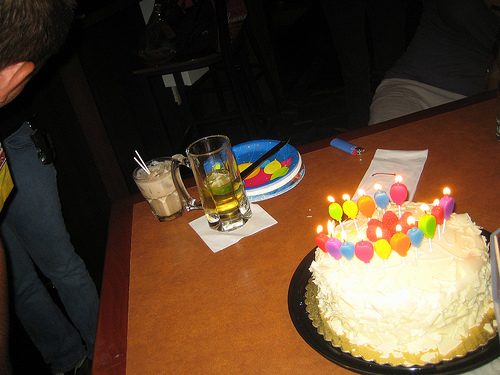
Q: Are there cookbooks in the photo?
A: No, there are no cookbooks.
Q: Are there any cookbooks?
A: No, there are no cookbooks.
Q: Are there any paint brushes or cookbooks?
A: No, there are no cookbooks or paint brushes.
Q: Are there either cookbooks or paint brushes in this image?
A: No, there are no cookbooks or paint brushes.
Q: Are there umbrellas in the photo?
A: No, there are no umbrellas.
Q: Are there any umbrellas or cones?
A: No, there are no umbrellas or cones.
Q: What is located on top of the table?
A: The paper is on top of the table.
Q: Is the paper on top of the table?
A: Yes, the paper is on top of the table.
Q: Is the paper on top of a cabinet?
A: No, the paper is on top of the table.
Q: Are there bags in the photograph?
A: No, there are no bags.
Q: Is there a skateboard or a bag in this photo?
A: No, there are no bags or skateboards.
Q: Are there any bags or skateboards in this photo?
A: No, there are no bags or skateboards.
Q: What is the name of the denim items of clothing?
A: The clothing items are jeans.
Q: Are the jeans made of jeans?
A: Yes, the jeans are made of jeans.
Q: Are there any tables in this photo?
A: Yes, there is a table.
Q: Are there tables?
A: Yes, there is a table.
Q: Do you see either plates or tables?
A: Yes, there is a table.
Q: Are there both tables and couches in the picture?
A: No, there is a table but no couches.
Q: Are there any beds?
A: No, there are no beds.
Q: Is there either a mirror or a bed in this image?
A: No, there are no beds or mirrors.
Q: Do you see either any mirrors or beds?
A: No, there are no beds or mirrors.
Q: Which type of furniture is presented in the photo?
A: The furniture is a table.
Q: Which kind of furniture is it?
A: The piece of furniture is a table.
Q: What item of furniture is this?
A: This is a table.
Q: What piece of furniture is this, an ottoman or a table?
A: This is a table.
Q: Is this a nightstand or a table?
A: This is a table.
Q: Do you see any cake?
A: Yes, there is a cake.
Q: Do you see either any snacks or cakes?
A: Yes, there is a cake.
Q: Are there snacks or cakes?
A: Yes, there is a cake.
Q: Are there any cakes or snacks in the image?
A: Yes, there is a cake.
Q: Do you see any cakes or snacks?
A: Yes, there is a cake.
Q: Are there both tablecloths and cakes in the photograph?
A: No, there is a cake but no tablecloths.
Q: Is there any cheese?
A: No, there is no cheese.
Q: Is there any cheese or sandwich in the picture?
A: No, there are no cheese or sandwiches.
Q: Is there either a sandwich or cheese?
A: No, there are no cheese or sandwiches.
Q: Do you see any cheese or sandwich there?
A: No, there are no cheese or sandwiches.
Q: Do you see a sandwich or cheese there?
A: No, there are no cheese or sandwiches.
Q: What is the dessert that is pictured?
A: The dessert is a cake.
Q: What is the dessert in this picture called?
A: The dessert is a cake.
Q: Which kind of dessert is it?
A: The dessert is a cake.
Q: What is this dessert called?
A: This is a cake.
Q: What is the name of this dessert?
A: This is a cake.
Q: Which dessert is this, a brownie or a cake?
A: This is a cake.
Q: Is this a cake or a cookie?
A: This is a cake.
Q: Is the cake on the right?
A: Yes, the cake is on the right of the image.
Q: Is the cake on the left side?
A: No, the cake is on the right of the image.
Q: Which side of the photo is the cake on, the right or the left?
A: The cake is on the right of the image.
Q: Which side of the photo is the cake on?
A: The cake is on the right of the image.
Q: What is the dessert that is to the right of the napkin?
A: The dessert is a cake.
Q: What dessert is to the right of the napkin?
A: The dessert is a cake.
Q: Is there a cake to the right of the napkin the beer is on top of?
A: Yes, there is a cake to the right of the napkin.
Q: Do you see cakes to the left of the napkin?
A: No, the cake is to the right of the napkin.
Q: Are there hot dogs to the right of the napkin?
A: No, there is a cake to the right of the napkin.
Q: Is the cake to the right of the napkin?
A: Yes, the cake is to the right of the napkin.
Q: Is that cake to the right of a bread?
A: No, the cake is to the right of the napkin.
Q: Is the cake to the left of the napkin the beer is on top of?
A: No, the cake is to the right of the napkin.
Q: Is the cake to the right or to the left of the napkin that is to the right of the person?
A: The cake is to the right of the napkin.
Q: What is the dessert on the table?
A: The dessert is a cake.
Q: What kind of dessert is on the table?
A: The dessert is a cake.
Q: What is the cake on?
A: The cake is on the table.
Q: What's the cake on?
A: The cake is on the table.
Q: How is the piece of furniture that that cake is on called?
A: The piece of furniture is a table.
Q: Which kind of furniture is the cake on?
A: The cake is on the table.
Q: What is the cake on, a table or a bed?
A: The cake is on a table.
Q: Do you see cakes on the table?
A: Yes, there is a cake on the table.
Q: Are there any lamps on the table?
A: No, there is a cake on the table.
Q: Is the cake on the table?
A: Yes, the cake is on the table.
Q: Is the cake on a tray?
A: No, the cake is on the table.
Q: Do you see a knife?
A: Yes, there is a knife.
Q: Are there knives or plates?
A: Yes, there is a knife.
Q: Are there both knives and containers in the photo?
A: No, there is a knife but no containers.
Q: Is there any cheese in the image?
A: No, there is no cheese.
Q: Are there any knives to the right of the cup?
A: Yes, there is a knife to the right of the cup.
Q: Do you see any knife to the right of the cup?
A: Yes, there is a knife to the right of the cup.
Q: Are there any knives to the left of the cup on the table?
A: No, the knife is to the right of the cup.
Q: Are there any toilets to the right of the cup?
A: No, there is a knife to the right of the cup.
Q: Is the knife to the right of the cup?
A: Yes, the knife is to the right of the cup.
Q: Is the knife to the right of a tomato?
A: No, the knife is to the right of the cup.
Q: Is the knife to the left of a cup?
A: No, the knife is to the right of a cup.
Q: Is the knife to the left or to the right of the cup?
A: The knife is to the right of the cup.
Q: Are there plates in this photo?
A: Yes, there is a plate.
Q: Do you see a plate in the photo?
A: Yes, there is a plate.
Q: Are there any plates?
A: Yes, there is a plate.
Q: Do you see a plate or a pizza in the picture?
A: Yes, there is a plate.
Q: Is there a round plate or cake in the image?
A: Yes, there is a round plate.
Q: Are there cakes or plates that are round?
A: Yes, the plate is round.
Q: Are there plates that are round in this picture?
A: Yes, there is a round plate.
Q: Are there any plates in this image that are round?
A: Yes, there is a plate that is round.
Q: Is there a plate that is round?
A: Yes, there is a plate that is round.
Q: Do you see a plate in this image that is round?
A: Yes, there is a plate that is round.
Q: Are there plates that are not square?
A: Yes, there is a round plate.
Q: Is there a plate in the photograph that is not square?
A: Yes, there is a round plate.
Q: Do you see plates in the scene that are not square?
A: Yes, there is a round plate.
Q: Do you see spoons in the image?
A: No, there are no spoons.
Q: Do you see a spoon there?
A: No, there are no spoons.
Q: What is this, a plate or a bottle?
A: This is a plate.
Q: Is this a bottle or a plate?
A: This is a plate.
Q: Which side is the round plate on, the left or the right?
A: The plate is on the right of the image.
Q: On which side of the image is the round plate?
A: The plate is on the right of the image.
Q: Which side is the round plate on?
A: The plate is on the right of the image.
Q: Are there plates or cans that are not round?
A: No, there is a plate but it is round.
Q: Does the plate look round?
A: Yes, the plate is round.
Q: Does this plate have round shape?
A: Yes, the plate is round.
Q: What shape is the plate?
A: The plate is round.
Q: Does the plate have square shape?
A: No, the plate is round.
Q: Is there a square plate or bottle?
A: No, there is a plate but it is round.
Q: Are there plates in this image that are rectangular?
A: No, there is a plate but it is round.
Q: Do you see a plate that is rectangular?
A: No, there is a plate but it is round.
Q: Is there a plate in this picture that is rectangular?
A: No, there is a plate but it is round.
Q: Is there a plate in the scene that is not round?
A: No, there is a plate but it is round.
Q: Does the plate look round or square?
A: The plate is round.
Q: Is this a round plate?
A: Yes, this is a round plate.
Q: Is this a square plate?
A: No, this is a round plate.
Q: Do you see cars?
A: No, there are no cars.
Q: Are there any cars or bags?
A: No, there are no cars or bags.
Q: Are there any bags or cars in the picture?
A: No, there are no cars or bags.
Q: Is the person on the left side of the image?
A: Yes, the person is on the left of the image.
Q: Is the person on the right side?
A: No, the person is on the left of the image.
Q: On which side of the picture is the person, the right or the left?
A: The person is on the left of the image.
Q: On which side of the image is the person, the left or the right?
A: The person is on the left of the image.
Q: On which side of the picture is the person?
A: The person is on the left of the image.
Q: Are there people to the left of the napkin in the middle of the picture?
A: Yes, there is a person to the left of the napkin.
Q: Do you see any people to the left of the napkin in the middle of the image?
A: Yes, there is a person to the left of the napkin.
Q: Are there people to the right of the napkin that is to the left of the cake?
A: No, the person is to the left of the napkin.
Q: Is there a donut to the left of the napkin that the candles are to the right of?
A: No, there is a person to the left of the napkin.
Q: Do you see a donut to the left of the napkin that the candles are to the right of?
A: No, there is a person to the left of the napkin.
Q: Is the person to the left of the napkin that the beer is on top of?
A: Yes, the person is to the left of the napkin.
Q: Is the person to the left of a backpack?
A: No, the person is to the left of the napkin.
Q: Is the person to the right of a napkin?
A: No, the person is to the left of a napkin.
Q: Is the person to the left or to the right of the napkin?
A: The person is to the left of the napkin.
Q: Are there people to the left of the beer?
A: Yes, there is a person to the left of the beer.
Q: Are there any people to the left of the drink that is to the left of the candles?
A: Yes, there is a person to the left of the beer.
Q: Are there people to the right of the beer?
A: No, the person is to the left of the beer.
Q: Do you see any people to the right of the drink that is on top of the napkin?
A: No, the person is to the left of the beer.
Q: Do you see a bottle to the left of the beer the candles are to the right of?
A: No, there is a person to the left of the beer.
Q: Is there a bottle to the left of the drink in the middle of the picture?
A: No, there is a person to the left of the beer.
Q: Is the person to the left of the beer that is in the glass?
A: Yes, the person is to the left of the beer.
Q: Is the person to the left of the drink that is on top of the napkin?
A: Yes, the person is to the left of the beer.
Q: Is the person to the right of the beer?
A: No, the person is to the left of the beer.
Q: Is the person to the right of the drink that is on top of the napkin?
A: No, the person is to the left of the beer.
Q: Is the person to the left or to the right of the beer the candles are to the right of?
A: The person is to the left of the beer.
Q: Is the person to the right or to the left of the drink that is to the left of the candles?
A: The person is to the left of the beer.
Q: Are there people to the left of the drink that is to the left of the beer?
A: Yes, there is a person to the left of the drink.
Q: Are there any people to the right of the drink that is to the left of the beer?
A: No, the person is to the left of the drink.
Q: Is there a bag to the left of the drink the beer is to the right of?
A: No, there is a person to the left of the drink.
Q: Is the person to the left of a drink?
A: Yes, the person is to the left of a drink.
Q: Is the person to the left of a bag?
A: No, the person is to the left of a drink.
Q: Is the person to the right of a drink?
A: No, the person is to the left of a drink.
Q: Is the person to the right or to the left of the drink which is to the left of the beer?
A: The person is to the left of the drink.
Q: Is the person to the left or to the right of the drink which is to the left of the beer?
A: The person is to the left of the drink.